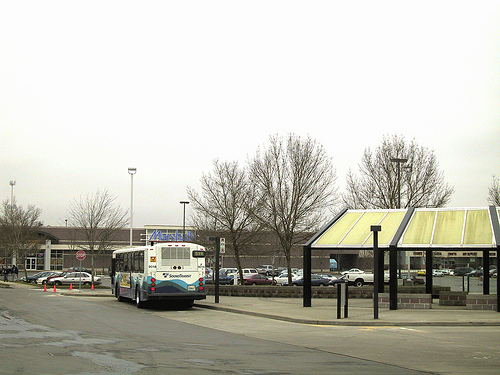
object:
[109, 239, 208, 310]
bus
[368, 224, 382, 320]
pole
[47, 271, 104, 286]
car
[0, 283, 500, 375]
road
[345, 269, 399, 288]
car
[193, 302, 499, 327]
edge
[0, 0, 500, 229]
sky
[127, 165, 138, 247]
pole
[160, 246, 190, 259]
window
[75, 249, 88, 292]
signpost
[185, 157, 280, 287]
tree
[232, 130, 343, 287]
tree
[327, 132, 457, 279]
tree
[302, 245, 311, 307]
stand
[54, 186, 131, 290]
trees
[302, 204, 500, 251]
roof